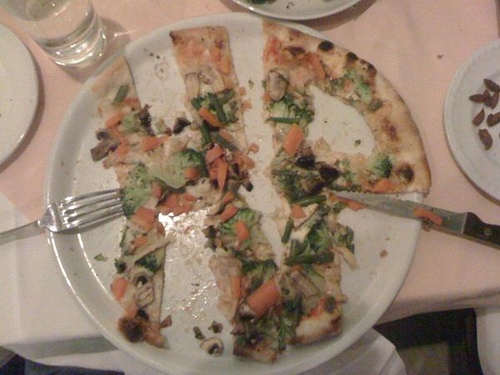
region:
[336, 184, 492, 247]
A knife is on the plate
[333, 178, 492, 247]
The knife has a black handle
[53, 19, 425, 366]
The plate is white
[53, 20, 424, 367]
The plate is round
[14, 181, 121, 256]
The fork is on the plate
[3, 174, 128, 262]
The fork is silver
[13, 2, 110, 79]
The glass is clear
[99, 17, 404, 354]
The dish is cut into pieces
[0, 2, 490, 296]
The cloth is pink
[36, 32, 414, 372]
The dish is hanging off the edge of the table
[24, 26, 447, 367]
food on a plate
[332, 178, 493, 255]
knife partially laying on a plate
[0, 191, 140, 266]
fork laying on a plate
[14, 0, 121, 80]
clear glass of water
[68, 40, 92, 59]
light reflecting off the water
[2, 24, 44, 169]
edge of a white plate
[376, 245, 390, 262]
small crumb on the plate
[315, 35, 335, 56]
black spot on the crust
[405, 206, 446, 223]
food on the blade of the knife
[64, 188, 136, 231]
tines of the fork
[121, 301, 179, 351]
This is a piece of meat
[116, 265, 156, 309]
This is a piece of meat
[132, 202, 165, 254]
This is a piece of meat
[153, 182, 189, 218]
This is a piece of meat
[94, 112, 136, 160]
This is a piece of meat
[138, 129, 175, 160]
This is a piece of meat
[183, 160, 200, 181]
This is a piece of meat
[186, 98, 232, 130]
This is a piece of meat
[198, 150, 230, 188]
This is a piece of meat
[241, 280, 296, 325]
This is a piece of meat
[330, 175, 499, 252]
Knife on the table.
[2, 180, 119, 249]
Silver metal fork on plate.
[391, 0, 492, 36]
Pink colored table cloth.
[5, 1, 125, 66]
Glass of water on the table.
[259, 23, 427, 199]
Slice of pizza on plate.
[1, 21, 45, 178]
White plate on table.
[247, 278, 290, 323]
Carrot on the pizza.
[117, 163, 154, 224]
Broccoli on top of the food.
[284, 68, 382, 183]
Hole in pizza slice.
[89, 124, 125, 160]
Mushroom on the plate.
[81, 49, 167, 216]
small slice of pizza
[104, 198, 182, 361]
small slice of pizza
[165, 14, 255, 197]
small slice of pizza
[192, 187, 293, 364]
small slice of pizza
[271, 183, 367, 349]
small slice of pizza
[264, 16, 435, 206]
small slice of pizza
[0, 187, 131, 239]
silver metal fork on plate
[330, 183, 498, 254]
silver metal knife on plate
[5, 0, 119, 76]
glass with water inside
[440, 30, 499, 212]
white plate with nuts on it